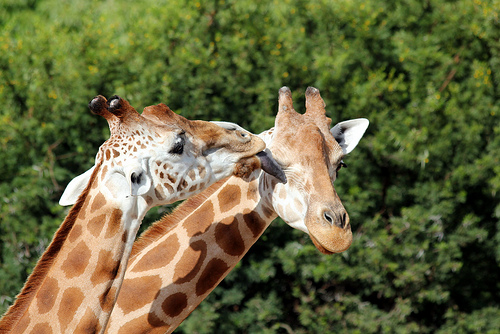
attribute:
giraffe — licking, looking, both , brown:
[11, 92, 287, 329]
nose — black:
[223, 121, 264, 151]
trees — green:
[150, 16, 468, 86]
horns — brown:
[83, 92, 136, 122]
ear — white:
[119, 160, 158, 197]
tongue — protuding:
[260, 150, 288, 184]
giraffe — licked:
[248, 94, 359, 272]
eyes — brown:
[168, 131, 196, 156]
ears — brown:
[67, 164, 167, 195]